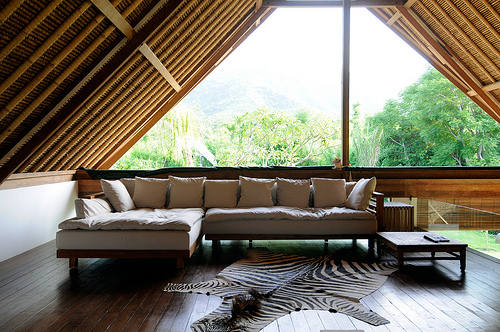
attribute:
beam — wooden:
[323, 9, 348, 169]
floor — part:
[63, 280, 165, 330]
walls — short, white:
[0, 157, 84, 269]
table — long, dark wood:
[358, 187, 470, 289]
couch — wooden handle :
[46, 167, 383, 251]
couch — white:
[50, 174, 387, 278]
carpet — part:
[170, 257, 415, 329]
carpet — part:
[160, 247, 396, 329]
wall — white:
[0, 177, 80, 261]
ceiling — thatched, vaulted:
[403, 0, 496, 95]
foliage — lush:
[127, 105, 472, 186]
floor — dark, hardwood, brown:
[0, 238, 499, 329]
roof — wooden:
[1, 4, 493, 164]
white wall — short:
[20, 210, 62, 240]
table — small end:
[379, 219, 479, 281]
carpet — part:
[252, 237, 429, 328]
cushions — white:
[100, 174, 377, 211]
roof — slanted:
[12, 8, 159, 116]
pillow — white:
[307, 176, 350, 211]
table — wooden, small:
[376, 226, 472, 281]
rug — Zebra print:
[159, 252, 405, 327]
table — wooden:
[378, 223, 468, 282]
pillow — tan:
[346, 172, 380, 212]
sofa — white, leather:
[55, 171, 382, 259]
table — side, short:
[369, 193, 427, 238]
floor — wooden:
[0, 204, 484, 315]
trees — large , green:
[159, 69, 497, 158]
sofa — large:
[41, 166, 383, 276]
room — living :
[4, 4, 484, 329]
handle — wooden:
[364, 184, 395, 218]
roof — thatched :
[3, 46, 161, 153]